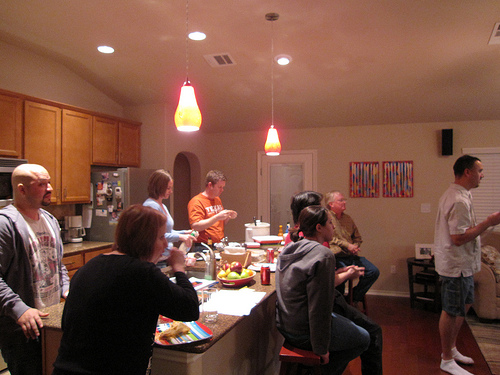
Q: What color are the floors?
A: Brown.